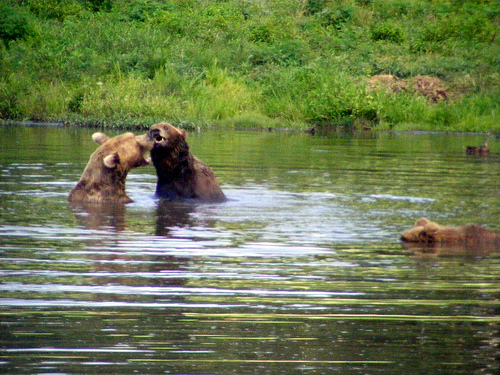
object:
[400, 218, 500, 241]
bear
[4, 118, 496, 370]
water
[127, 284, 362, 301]
ripple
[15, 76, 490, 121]
ground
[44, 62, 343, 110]
grass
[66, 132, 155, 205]
bears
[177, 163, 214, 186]
fur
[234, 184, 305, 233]
wave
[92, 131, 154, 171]
head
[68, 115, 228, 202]
two bears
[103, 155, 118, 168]
ears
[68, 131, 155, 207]
left bear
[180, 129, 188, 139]
ear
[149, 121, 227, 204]
right bear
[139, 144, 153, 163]
mouth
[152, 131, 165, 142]
mouth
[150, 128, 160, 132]
nose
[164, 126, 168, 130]
eye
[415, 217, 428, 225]
ears